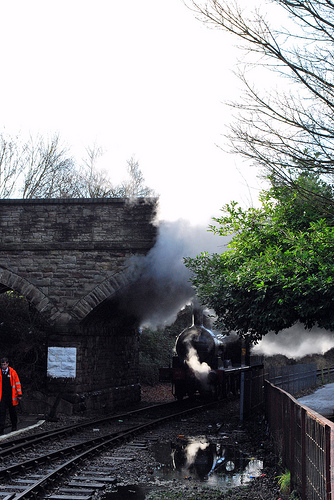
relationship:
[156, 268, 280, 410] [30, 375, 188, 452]
train has track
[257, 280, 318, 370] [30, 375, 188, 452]
steam on track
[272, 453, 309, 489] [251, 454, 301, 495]
grass in rocks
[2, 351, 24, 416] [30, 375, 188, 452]
man on track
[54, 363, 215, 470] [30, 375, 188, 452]
railroad has track